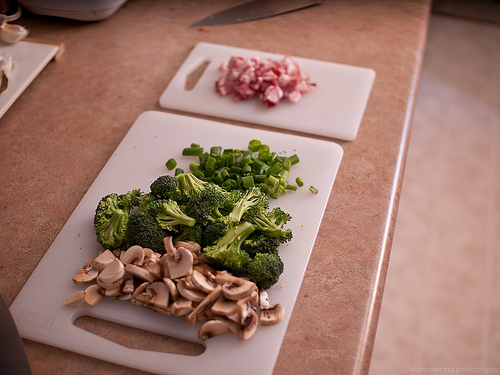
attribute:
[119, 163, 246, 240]
brocolli — cut, set, chopped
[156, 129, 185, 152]
board — white, plastic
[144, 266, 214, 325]
mushrooms — brown, chopped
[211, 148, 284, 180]
chives — chopped, cut, green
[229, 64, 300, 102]
meat — chopped, cooked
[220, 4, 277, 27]
knife — sharp, silver, visable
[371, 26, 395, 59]
table — brown, marble, pink